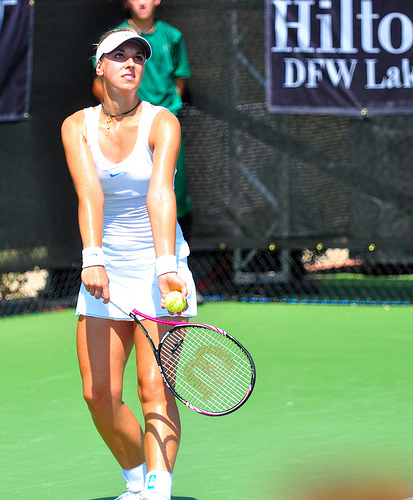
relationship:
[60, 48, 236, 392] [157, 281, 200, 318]
girl holding ball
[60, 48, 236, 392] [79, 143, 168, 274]
girl wearing outfit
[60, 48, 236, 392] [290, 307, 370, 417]
girl on court